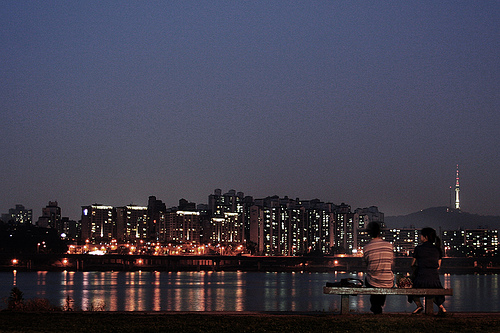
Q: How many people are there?
A: 2.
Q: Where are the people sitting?
A: On the bench.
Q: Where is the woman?
A: On the right.